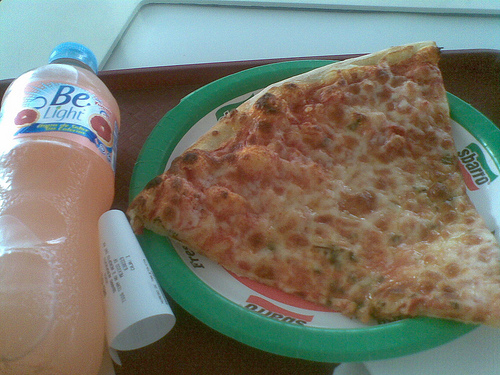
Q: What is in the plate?
A: A piece of cheese pizza.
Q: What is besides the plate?
A: A plastic bottle of fruit juice.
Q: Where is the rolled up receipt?
A: Between juice bottle and plate.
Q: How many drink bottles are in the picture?
A: One.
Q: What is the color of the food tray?
A: Brown.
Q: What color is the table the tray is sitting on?
A: White.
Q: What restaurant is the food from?
A: Sbarro.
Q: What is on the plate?
A: Pizza.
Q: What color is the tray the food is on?
A: Brown.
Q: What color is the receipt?
A: White.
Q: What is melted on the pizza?
A: Cheese.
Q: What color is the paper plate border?
A: Green.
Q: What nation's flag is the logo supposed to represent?
A: Italy.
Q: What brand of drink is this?
A: Be Light.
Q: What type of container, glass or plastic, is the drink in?
A: Plastic.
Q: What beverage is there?
A: Juice.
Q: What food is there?
A: Pizza.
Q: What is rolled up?
A: Receipt.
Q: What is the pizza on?
A: Plate.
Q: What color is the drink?
A: Pink.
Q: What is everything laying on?
A: Table.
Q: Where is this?
A: Kitchen.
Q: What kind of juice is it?
A: Grapefruit.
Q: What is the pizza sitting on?
A: A paper plate.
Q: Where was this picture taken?
A: At a restaurant.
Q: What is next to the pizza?
A: A bottled drink.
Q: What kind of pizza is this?
A: Cheese.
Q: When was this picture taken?
A: Daytime.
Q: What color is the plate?
A: Green and white.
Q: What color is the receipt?
A: White.